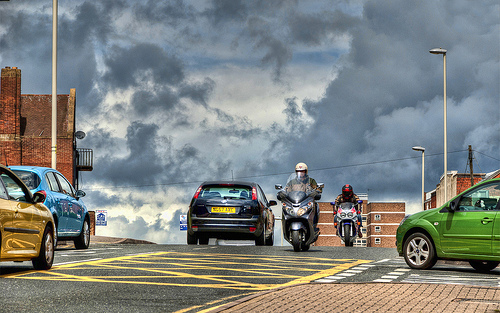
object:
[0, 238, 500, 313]
ground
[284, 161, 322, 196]
person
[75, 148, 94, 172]
balcony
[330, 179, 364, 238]
person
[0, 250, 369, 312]
street marking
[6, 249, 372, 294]
line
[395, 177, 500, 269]
car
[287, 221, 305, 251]
front tire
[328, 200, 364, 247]
bike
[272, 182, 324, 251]
bike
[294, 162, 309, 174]
helmet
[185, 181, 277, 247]
car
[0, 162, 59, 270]
vehicle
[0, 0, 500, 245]
sky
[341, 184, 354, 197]
helmet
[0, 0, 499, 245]
clouds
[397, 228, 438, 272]
tire